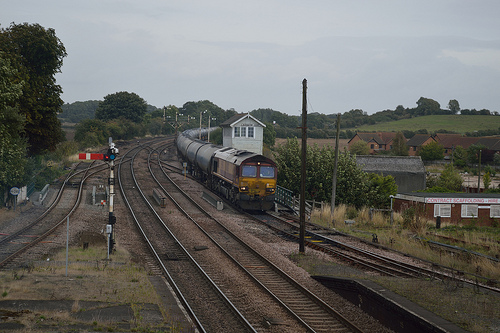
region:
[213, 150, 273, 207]
the train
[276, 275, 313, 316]
the train tracks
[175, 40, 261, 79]
the clouds are white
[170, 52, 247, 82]
the clouds in the sky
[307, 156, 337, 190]
the bush is green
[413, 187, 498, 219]
a building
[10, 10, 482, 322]
train rounding a curve in rural area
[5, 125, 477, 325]
train tracks leading to different routes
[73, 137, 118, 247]
black and white pole with red and white sign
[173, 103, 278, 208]
tall gray building with three windows on side of train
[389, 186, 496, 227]
low brick building with flat roof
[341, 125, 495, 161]
group of brown buildings with brown roofs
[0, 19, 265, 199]
trees along outer edge of train tracks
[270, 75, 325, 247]
railed ramp behind tall pole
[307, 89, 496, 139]
hilltop enclosed with trees and shrubs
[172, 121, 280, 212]
dirty red and yellow engine leading freight train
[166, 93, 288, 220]
this is a train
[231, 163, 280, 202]
yellow front of train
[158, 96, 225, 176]
tanks on the train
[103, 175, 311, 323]
a set of train tracks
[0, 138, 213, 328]
the train tracks split up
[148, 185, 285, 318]
gravel on the tracks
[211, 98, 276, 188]
building next to train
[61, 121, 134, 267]
a pole next to tracks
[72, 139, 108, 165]
a red sign on pole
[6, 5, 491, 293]
a hazy overcast day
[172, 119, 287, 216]
black train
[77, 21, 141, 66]
white clouds in blue sky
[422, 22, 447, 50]
white clouds in blue sky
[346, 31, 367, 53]
white clouds in blue sky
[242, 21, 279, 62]
white clouds in blue sky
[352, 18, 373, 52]
white clouds in blue sky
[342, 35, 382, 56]
white clouds in blue sky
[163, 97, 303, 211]
this is a train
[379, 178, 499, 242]
this is a house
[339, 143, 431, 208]
this is a house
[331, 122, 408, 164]
this is a house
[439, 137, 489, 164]
this is a house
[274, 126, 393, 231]
this is a tree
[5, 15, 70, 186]
this is a tree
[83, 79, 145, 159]
this is a tree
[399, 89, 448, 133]
this is a tree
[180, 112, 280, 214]
yellow and black train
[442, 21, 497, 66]
white clouds in blue sky